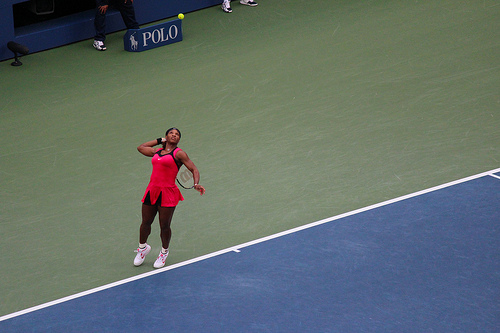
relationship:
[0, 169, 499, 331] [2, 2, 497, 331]
court on ground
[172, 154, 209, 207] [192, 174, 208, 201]
racket in hand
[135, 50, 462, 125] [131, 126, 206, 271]
green court behind lady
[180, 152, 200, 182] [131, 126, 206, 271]
arm of lady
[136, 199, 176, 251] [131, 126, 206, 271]
legs of lady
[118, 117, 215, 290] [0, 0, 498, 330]
tennis player on court